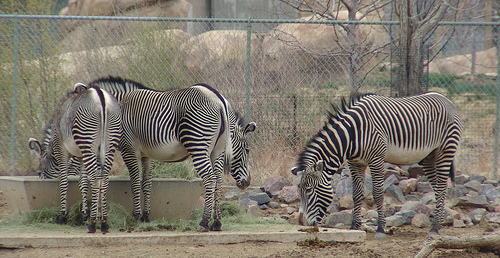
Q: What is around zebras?
A: Chain link fence.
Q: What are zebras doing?
A: Eating from trough.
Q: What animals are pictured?
A: Zebras.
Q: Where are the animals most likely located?
A: In a zoo.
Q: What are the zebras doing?
A: Eating something off of the ground and drinking water.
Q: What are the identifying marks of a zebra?
A: Black and white stripes.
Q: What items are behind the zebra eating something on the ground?
A: A large pile of rocks.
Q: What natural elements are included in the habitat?
A: Dirt, rocks and trees.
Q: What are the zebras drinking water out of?
A: A cement trough.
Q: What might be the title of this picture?
A: Three zebras stand together.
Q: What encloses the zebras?
A: A chain link fence.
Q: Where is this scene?
A: Zoo.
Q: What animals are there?
A: Zebra.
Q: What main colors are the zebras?
A: Black and white.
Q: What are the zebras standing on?
A: Concrete.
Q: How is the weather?
A: Fair.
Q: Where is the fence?
A: Behind zebras.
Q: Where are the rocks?
A: In pile.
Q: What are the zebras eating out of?
A: Trough.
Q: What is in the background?
A: Trees.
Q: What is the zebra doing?
A: Grazing.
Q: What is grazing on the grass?
A: A zebra.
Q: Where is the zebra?
A: Grazing.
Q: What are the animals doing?
A: Feeding.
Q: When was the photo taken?
A: Daytime.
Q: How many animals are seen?
A: Three.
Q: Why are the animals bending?
A: They are feeding.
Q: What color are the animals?
A: Black and white.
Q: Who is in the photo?
A: No one.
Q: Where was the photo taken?
A: A park.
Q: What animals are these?
A: Zebras.